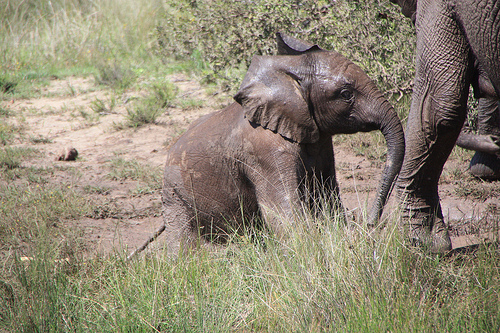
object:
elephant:
[122, 30, 407, 265]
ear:
[232, 54, 321, 145]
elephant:
[390, 1, 499, 261]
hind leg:
[161, 197, 197, 262]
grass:
[0, 165, 499, 331]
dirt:
[9, 70, 225, 261]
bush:
[154, 2, 421, 104]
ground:
[1, 1, 499, 253]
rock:
[54, 145, 80, 162]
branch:
[15, 252, 78, 265]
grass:
[0, 1, 169, 77]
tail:
[123, 220, 169, 264]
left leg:
[466, 77, 499, 180]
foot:
[399, 213, 455, 251]